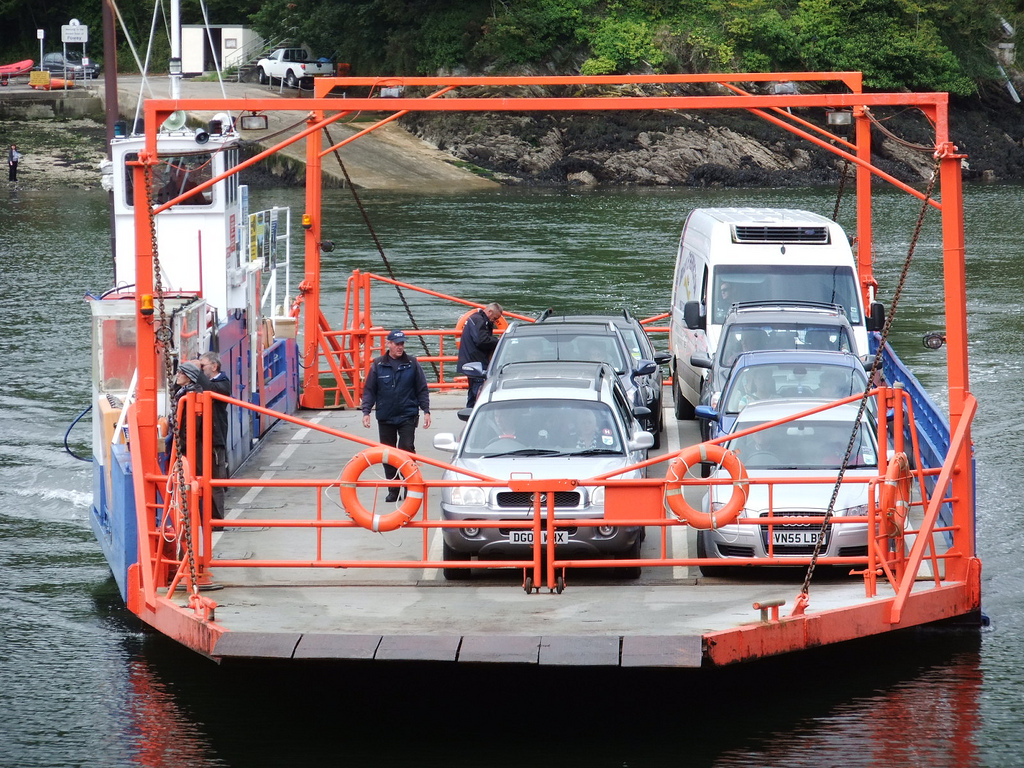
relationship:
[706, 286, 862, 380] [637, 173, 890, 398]
suv by van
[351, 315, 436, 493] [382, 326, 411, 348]
man on hat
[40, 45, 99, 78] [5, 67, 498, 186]
car at top of ramp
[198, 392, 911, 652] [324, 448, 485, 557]
gate with life preservers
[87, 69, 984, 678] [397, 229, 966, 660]
ferry with cars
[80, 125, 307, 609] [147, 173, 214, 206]
building has window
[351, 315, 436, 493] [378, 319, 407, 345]
man wears hat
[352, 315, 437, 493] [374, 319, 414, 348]
man wears hat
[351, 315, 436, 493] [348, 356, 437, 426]
man wears jacket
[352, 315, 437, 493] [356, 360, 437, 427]
man wears jacket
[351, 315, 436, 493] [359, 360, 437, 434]
man wears jacket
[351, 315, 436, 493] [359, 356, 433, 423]
man wears jacket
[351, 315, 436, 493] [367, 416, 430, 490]
man wears pants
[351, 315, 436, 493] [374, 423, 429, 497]
man wears pants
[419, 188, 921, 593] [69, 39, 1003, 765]
vehicles on ferry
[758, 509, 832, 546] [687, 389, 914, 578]
license plate on car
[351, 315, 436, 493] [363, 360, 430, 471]
man wears uniform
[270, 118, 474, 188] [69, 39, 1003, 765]
road behind ferry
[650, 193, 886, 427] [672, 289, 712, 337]
van has mirror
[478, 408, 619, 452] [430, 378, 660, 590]
people in car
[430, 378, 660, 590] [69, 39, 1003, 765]
car on ferry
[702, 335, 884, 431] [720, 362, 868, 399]
car has windshield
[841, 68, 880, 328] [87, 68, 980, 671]
post on ferry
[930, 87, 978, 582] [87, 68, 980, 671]
post on ferry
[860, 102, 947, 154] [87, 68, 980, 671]
rope on ferry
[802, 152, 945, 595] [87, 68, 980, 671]
rope on ferry